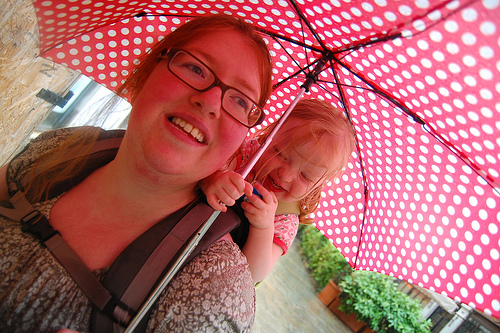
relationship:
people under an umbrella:
[125, 17, 353, 256] [366, 20, 485, 219]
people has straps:
[0, 12, 356, 333] [9, 184, 176, 292]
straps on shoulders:
[9, 184, 176, 292] [65, 126, 125, 155]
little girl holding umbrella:
[263, 99, 353, 204] [366, 20, 485, 219]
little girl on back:
[263, 99, 353, 204] [234, 225, 246, 240]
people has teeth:
[0, 12, 356, 333] [175, 119, 199, 137]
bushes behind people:
[306, 238, 334, 282] [125, 17, 353, 256]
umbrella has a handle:
[366, 20, 485, 219] [186, 235, 204, 261]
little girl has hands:
[263, 99, 353, 204] [213, 178, 274, 224]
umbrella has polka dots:
[366, 20, 485, 219] [435, 25, 479, 53]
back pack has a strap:
[231, 204, 242, 218] [57, 243, 91, 295]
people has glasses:
[0, 12, 356, 333] [174, 52, 266, 121]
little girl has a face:
[263, 99, 353, 204] [269, 145, 320, 190]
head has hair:
[153, 31, 261, 144] [193, 12, 260, 32]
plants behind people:
[346, 270, 405, 326] [125, 17, 353, 256]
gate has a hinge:
[405, 282, 442, 310] [437, 302, 457, 323]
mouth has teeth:
[163, 110, 212, 150] [175, 119, 199, 137]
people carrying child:
[0, 12, 356, 333] [263, 99, 353, 204]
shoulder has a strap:
[207, 239, 238, 267] [57, 243, 91, 295]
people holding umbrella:
[0, 12, 356, 333] [366, 20, 485, 219]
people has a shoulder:
[0, 12, 356, 333] [207, 239, 238, 267]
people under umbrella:
[125, 17, 353, 256] [366, 20, 485, 219]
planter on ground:
[317, 282, 342, 308] [284, 298, 309, 326]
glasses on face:
[174, 52, 266, 121] [153, 31, 261, 144]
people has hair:
[0, 12, 356, 333] [193, 12, 260, 32]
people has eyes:
[0, 12, 356, 333] [174, 52, 266, 121]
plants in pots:
[346, 270, 405, 326] [330, 300, 352, 323]